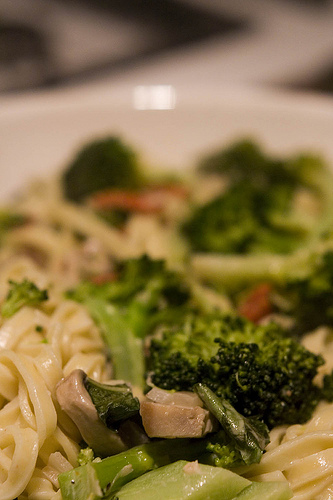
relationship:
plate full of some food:
[0, 82, 331, 197] [24, 247, 284, 435]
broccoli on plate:
[151, 313, 321, 429] [0, 79, 333, 177]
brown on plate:
[139, 382, 212, 441] [0, 79, 331, 207]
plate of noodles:
[8, 57, 331, 245] [1, 298, 102, 497]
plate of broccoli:
[8, 57, 331, 245] [80, 235, 327, 452]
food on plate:
[1, 134, 331, 497] [0, 82, 331, 197]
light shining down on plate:
[128, 81, 183, 110] [15, 83, 319, 192]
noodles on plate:
[18, 353, 57, 408] [1, 82, 332, 496]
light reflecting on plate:
[128, 81, 183, 110] [2, 77, 308, 172]